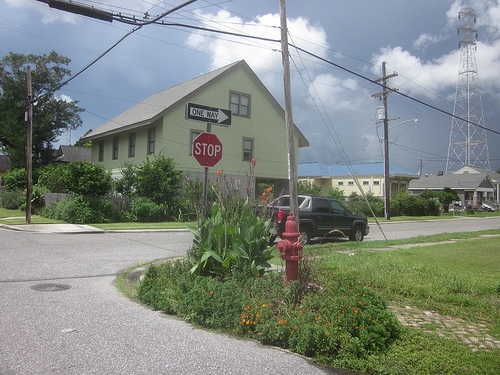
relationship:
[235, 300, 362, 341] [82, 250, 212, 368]
flowers on roadside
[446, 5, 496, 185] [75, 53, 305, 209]
pylon next to house